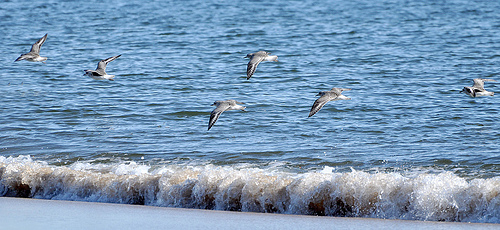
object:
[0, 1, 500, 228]
ocean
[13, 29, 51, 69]
bird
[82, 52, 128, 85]
bird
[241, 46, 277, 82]
bird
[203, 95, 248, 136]
bird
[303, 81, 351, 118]
bird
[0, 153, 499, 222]
surf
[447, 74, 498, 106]
bird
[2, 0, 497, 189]
water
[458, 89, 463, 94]
beak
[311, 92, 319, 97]
beak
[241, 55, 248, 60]
beak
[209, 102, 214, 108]
beak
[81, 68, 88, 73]
beak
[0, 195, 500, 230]
beach